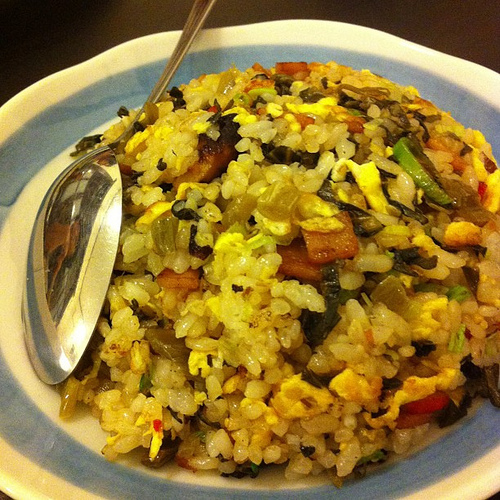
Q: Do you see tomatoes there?
A: No, there are no tomatoes.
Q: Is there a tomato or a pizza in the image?
A: No, there are no tomatoes or pizzas.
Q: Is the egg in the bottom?
A: Yes, the egg is in the bottom of the image.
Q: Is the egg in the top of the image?
A: No, the egg is in the bottom of the image.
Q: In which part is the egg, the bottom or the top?
A: The egg is in the bottom of the image.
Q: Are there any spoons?
A: Yes, there is a spoon.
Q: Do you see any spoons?
A: Yes, there is a spoon.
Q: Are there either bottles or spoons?
A: Yes, there is a spoon.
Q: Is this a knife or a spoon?
A: This is a spoon.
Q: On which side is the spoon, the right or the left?
A: The spoon is on the left of the image.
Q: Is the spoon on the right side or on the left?
A: The spoon is on the left of the image.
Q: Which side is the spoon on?
A: The spoon is on the left of the image.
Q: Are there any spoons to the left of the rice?
A: Yes, there is a spoon to the left of the rice.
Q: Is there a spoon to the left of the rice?
A: Yes, there is a spoon to the left of the rice.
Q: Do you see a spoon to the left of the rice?
A: Yes, there is a spoon to the left of the rice.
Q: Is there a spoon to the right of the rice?
A: No, the spoon is to the left of the rice.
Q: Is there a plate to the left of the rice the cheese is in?
A: No, there is a spoon to the left of the rice.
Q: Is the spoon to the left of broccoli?
A: No, the spoon is to the left of the rice.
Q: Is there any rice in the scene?
A: Yes, there is rice.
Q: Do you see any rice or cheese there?
A: Yes, there is rice.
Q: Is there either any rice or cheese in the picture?
A: Yes, there is rice.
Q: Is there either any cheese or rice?
A: Yes, there is rice.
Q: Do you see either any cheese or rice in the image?
A: Yes, there is rice.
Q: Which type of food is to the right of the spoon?
A: The food is rice.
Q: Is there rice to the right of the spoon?
A: Yes, there is rice to the right of the spoon.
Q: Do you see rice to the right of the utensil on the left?
A: Yes, there is rice to the right of the spoon.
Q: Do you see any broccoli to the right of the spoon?
A: No, there is rice to the right of the spoon.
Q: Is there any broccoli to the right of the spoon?
A: No, there is rice to the right of the spoon.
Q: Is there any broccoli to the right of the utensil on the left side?
A: No, there is rice to the right of the spoon.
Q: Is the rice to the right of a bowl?
A: No, the rice is to the right of the spoon.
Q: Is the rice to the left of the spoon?
A: No, the rice is to the right of the spoon.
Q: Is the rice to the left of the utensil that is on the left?
A: No, the rice is to the right of the spoon.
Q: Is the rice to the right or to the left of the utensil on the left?
A: The rice is to the right of the spoon.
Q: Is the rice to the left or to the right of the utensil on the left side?
A: The rice is to the right of the spoon.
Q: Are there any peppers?
A: Yes, there are peppers.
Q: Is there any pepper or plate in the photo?
A: Yes, there are peppers.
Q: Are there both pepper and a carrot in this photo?
A: No, there are peppers but no carrots.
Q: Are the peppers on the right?
A: Yes, the peppers are on the right of the image.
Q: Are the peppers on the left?
A: No, the peppers are on the right of the image.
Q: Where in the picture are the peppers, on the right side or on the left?
A: The peppers are on the right of the image.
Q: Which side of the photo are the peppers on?
A: The peppers are on the right of the image.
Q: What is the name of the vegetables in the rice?
A: The vegetables are peppers.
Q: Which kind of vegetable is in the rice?
A: The vegetables are peppers.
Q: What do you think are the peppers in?
A: The peppers are in the rice.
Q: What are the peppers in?
A: The peppers are in the rice.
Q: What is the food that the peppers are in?
A: The food is rice.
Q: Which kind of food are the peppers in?
A: The peppers are in the rice.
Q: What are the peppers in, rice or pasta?
A: The peppers are in rice.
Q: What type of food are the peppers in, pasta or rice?
A: The peppers are in rice.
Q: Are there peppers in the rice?
A: Yes, there are peppers in the rice.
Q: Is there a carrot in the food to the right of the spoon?
A: No, there are peppers in the rice.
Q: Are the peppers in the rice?
A: Yes, the peppers are in the rice.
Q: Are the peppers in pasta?
A: No, the peppers are in the rice.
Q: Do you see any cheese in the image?
A: Yes, there is cheese.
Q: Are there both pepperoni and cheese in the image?
A: No, there is cheese but no pepperoni.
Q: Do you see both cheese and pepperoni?
A: No, there is cheese but no pepperoni.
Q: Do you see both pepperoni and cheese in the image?
A: No, there is cheese but no pepperoni.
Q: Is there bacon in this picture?
A: No, there is no bacon.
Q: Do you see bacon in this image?
A: No, there is no bacon.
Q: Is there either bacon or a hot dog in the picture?
A: No, there are no bacon or hot dogs.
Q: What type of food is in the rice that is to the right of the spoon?
A: The food is cheese.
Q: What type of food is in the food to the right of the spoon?
A: The food is cheese.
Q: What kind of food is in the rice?
A: The food is cheese.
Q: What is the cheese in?
A: The cheese is in the rice.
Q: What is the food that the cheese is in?
A: The food is rice.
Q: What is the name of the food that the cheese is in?
A: The food is rice.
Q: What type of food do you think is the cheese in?
A: The cheese is in the rice.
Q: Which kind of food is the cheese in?
A: The cheese is in the rice.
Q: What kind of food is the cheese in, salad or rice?
A: The cheese is in rice.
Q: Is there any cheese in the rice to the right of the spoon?
A: Yes, there is cheese in the rice.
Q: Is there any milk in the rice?
A: No, there is cheese in the rice.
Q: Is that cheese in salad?
A: No, the cheese is in the rice.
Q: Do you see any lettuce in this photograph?
A: No, there is no lettuce.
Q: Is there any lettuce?
A: No, there is no lettuce.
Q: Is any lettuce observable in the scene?
A: No, there is no lettuce.